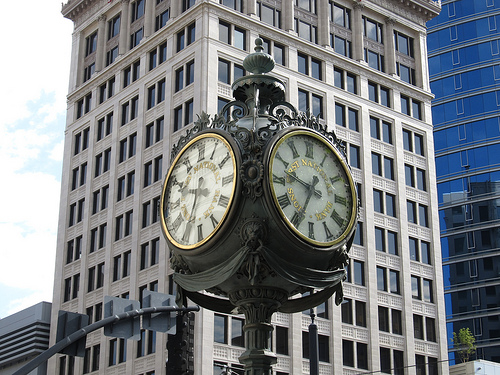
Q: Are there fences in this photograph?
A: No, there are no fences.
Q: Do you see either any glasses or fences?
A: No, there are no fences or glasses.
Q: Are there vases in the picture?
A: No, there are no vases.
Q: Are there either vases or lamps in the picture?
A: No, there are no vases or lamps.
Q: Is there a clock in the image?
A: Yes, there is a clock.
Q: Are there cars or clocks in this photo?
A: Yes, there is a clock.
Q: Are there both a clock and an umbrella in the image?
A: No, there is a clock but no umbrellas.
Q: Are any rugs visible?
A: No, there are no rugs.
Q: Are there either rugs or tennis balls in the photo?
A: No, there are no rugs or tennis balls.